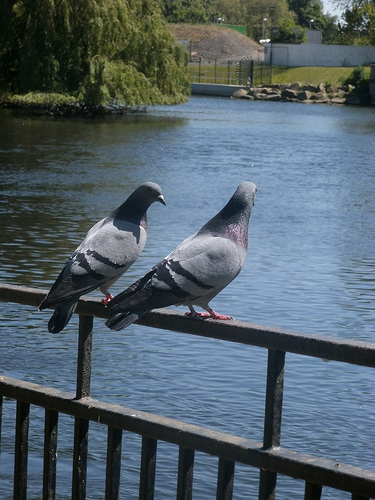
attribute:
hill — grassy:
[186, 54, 374, 98]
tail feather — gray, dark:
[46, 300, 76, 334]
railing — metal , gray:
[2, 282, 373, 498]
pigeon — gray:
[99, 180, 270, 335]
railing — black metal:
[1, 281, 374, 372]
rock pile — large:
[226, 78, 354, 107]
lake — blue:
[5, 67, 373, 356]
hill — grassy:
[184, 60, 373, 87]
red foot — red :
[36, 167, 169, 335]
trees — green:
[0, 0, 194, 108]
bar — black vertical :
[262, 347, 285, 447]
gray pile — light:
[253, 74, 356, 104]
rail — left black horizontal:
[2, 285, 372, 498]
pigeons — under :
[39, 162, 257, 370]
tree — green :
[0, 0, 194, 114]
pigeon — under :
[101, 178, 259, 330]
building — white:
[263, 34, 373, 67]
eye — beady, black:
[143, 182, 152, 203]